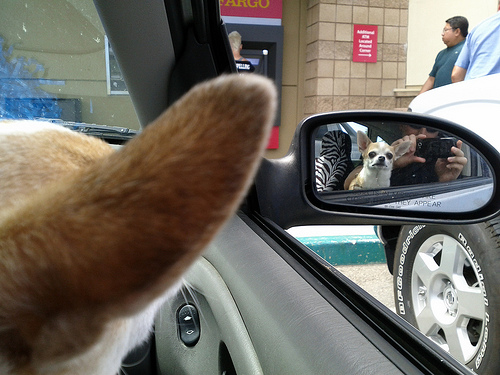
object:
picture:
[378, 118, 473, 190]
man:
[418, 15, 469, 94]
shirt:
[428, 38, 466, 90]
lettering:
[357, 29, 375, 57]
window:
[190, 1, 493, 362]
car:
[0, 0, 479, 374]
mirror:
[311, 116, 496, 218]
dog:
[343, 129, 413, 191]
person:
[388, 124, 467, 184]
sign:
[353, 24, 379, 64]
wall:
[317, 2, 409, 109]